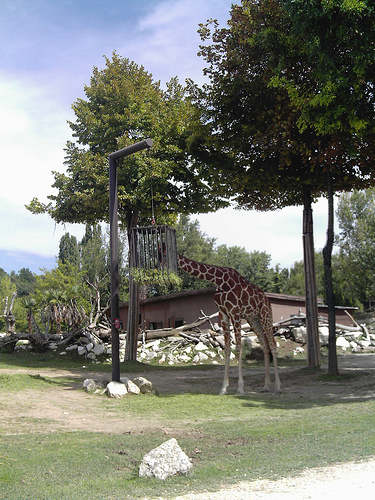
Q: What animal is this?
A: Giraffe.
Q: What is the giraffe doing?
A: Eating.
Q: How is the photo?
A: Clear.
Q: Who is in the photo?
A: Nobody.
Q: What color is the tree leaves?
A: Green.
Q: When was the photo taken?
A: Daytime.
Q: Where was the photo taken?
A: At the zoo.